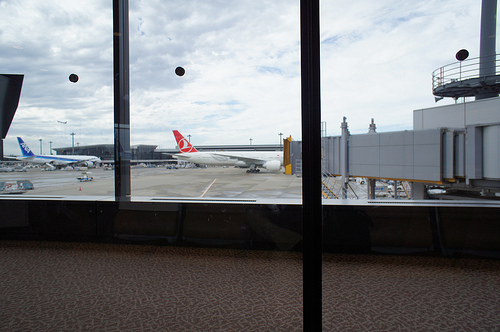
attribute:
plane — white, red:
[171, 127, 283, 175]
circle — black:
[174, 67, 186, 77]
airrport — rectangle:
[0, 129, 499, 207]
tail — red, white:
[174, 128, 201, 154]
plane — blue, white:
[6, 136, 102, 172]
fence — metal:
[295, 129, 461, 183]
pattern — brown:
[2, 236, 500, 332]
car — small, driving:
[77, 167, 94, 183]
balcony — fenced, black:
[431, 51, 499, 102]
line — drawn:
[201, 175, 217, 200]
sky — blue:
[0, 2, 499, 150]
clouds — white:
[10, 2, 478, 152]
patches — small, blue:
[209, 8, 418, 115]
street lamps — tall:
[36, 129, 79, 155]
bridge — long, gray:
[163, 145, 285, 154]